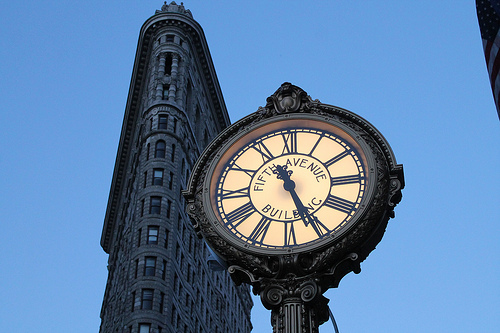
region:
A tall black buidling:
[122, 23, 205, 330]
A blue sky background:
[393, 245, 497, 298]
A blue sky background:
[320, 8, 461, 95]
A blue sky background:
[211, 10, 293, 94]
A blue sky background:
[4, 239, 94, 308]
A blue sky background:
[1, 185, 123, 237]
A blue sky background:
[8, 92, 139, 202]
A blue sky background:
[5, 3, 137, 69]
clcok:
[195, 73, 380, 275]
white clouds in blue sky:
[31, 34, 81, 94]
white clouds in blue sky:
[4, 175, 55, 239]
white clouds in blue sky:
[42, 86, 84, 113]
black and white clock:
[198, 75, 360, 259]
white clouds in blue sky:
[369, 241, 414, 276]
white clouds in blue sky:
[422, 183, 444, 215]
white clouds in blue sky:
[297, 49, 338, 79]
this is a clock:
[209, 124, 396, 265]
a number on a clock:
[299, 120, 326, 150]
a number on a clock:
[318, 193, 363, 216]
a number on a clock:
[226, 188, 250, 227]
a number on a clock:
[254, 210, 275, 248]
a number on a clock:
[286, 216, 297, 248]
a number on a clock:
[226, 160, 264, 173]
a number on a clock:
[331, 171, 358, 183]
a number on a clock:
[239, 214, 271, 239]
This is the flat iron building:
[67, 8, 282, 328]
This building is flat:
[75, 15, 268, 331]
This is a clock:
[162, 81, 409, 313]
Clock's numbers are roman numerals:
[215, 127, 372, 249]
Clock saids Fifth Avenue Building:
[243, 143, 330, 224]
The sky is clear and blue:
[7, 3, 497, 332]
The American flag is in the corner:
[466, 1, 498, 125]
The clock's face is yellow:
[215, 115, 366, 257]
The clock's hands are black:
[270, 158, 329, 239]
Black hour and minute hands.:
[276, 163, 321, 239]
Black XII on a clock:
[280, 131, 297, 155]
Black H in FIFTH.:
[267, 163, 278, 173]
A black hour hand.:
[276, 164, 308, 225]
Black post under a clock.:
[270, 288, 317, 332]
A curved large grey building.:
[98, 1, 254, 332]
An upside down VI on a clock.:
[282, 220, 297, 249]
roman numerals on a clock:
[251, 137, 275, 176]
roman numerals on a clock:
[278, 130, 299, 155]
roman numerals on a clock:
[311, 128, 324, 158]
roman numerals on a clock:
[320, 143, 345, 174]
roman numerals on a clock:
[328, 169, 359, 189]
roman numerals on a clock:
[320, 190, 355, 215]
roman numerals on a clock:
[306, 208, 331, 235]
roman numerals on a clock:
[277, 218, 302, 245]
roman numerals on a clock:
[246, 214, 272, 244]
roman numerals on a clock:
[226, 202, 258, 229]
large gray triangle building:
[65, 12, 224, 331]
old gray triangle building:
[72, 20, 233, 321]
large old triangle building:
[115, 26, 208, 331]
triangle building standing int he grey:
[86, 28, 221, 321]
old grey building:
[98, 5, 218, 321]